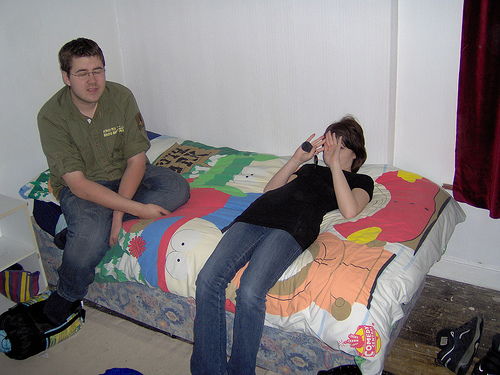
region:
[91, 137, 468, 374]
South Park bed comforter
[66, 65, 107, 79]
glasses on the man's face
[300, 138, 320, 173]
sunglasses in the woman's hand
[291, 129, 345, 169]
hands over the woman's face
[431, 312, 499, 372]
black and gray shoes on the floor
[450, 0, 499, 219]
red window curtain on the wall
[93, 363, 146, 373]
blue shirt on the floor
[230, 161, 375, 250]
black shirt on the woman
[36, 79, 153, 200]
green shirt on the man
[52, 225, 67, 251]
man wearing a black sock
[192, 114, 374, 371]
Girl hiding her face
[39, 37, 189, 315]
Young man with his eyes closed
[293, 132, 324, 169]
Hand holding car keys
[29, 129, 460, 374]
Single bed with 2 people on it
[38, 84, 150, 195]
Green button down shirt with rolled up sleeves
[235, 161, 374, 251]
Black short sleeved top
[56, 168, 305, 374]
Two pairs of blue jeans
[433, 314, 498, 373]
Black sneakers sitting on the floor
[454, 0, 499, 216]
Left edge of red curtain panel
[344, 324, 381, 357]
Comedy channel logo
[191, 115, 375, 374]
girl laying across a bed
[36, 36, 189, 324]
boy sitting on a bed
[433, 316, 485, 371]
black high top sneaker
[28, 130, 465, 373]
mattress and box-spring on the floor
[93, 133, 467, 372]
south park bed comforter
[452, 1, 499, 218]
dark red window coverings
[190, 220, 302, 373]
pair of woman's jeans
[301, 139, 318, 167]
car keys and fob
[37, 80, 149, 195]
green mens shirt worn by boy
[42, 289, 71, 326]
dark sock on a foot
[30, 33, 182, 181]
A man in a green shirt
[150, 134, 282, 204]
A bed with a south park blanket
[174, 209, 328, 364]
The legs of a person on a bed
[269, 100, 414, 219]
A girl covering her face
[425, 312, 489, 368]
A shoe on the floor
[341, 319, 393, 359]
A logo for comedy central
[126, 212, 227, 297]
A cartoon character with a blue hat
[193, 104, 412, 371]
A girl laying in a bed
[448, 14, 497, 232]
Red curtains in front of a window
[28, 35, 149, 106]
A guy who is blinking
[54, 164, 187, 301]
blue jeans on a man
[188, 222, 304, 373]
blue jeans on a woman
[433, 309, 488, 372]
a black shoe on the floor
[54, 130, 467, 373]
a Southpark comforter on a bed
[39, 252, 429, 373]
box springs under a bed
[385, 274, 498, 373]
a worn hardwood floor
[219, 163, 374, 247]
a black shirt on a woman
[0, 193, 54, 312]
a white shelf next to a bed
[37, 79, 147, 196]
an olive green shirt on a man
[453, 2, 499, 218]
a red curtain in a window